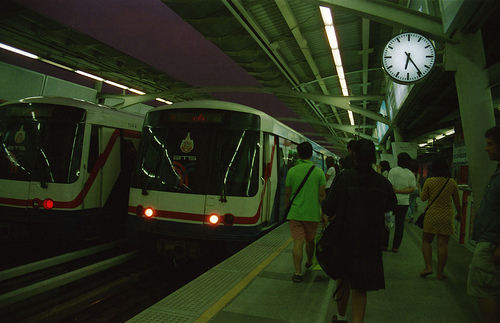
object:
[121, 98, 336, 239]
train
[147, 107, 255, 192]
window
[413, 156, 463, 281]
person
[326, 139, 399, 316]
person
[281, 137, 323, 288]
person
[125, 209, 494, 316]
sidewalk